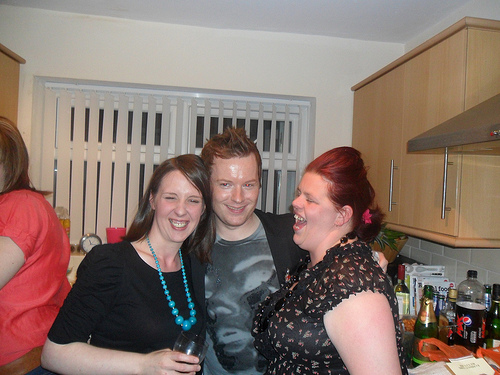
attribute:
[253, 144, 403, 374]
lady — laughing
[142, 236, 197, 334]
necklace — blue, pearl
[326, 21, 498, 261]
cupboard — wooden